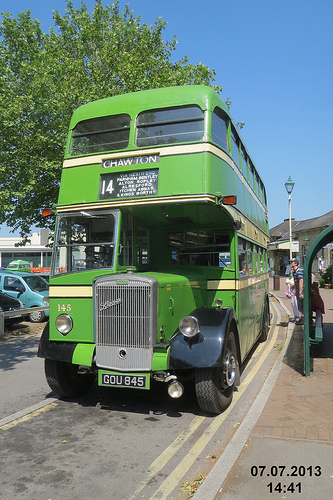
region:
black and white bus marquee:
[101, 171, 161, 200]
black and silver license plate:
[100, 368, 146, 388]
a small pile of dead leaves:
[175, 475, 201, 492]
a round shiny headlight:
[167, 377, 186, 400]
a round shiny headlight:
[177, 315, 199, 336]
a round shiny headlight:
[54, 310, 75, 335]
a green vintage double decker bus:
[33, 85, 274, 422]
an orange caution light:
[223, 193, 236, 206]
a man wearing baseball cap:
[288, 256, 310, 324]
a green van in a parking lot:
[2, 272, 48, 310]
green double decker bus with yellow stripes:
[44, 81, 269, 401]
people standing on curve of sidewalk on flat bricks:
[201, 250, 326, 492]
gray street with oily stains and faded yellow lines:
[0, 286, 286, 493]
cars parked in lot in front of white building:
[0, 230, 61, 328]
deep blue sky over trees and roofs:
[0, 1, 326, 233]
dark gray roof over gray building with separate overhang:
[268, 210, 326, 275]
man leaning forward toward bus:
[258, 243, 300, 322]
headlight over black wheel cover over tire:
[169, 296, 239, 413]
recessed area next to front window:
[52, 203, 228, 272]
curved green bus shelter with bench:
[301, 221, 329, 377]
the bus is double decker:
[58, 91, 299, 384]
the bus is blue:
[38, 96, 275, 404]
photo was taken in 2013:
[250, 460, 322, 496]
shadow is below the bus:
[97, 393, 175, 421]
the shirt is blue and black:
[292, 269, 304, 297]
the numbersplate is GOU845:
[102, 374, 147, 385]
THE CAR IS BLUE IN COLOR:
[4, 273, 53, 323]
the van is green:
[12, 260, 37, 270]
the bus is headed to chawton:
[100, 152, 173, 166]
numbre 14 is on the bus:
[96, 175, 119, 197]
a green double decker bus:
[35, 79, 273, 416]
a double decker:
[34, 82, 274, 417]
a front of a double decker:
[34, 83, 220, 415]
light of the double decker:
[220, 193, 238, 206]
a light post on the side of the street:
[278, 173, 300, 257]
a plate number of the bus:
[100, 373, 146, 389]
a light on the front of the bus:
[176, 315, 202, 340]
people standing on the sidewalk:
[282, 254, 308, 326]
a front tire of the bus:
[191, 326, 239, 416]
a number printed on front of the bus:
[54, 301, 73, 312]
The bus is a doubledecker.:
[34, 84, 275, 421]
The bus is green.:
[32, 82, 274, 417]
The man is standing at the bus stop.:
[265, 207, 332, 389]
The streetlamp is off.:
[282, 170, 297, 325]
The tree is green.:
[0, 0, 220, 259]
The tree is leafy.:
[1, 0, 221, 264]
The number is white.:
[100, 174, 107, 197]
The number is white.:
[104, 177, 115, 197]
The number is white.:
[123, 372, 131, 386]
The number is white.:
[136, 375, 145, 387]